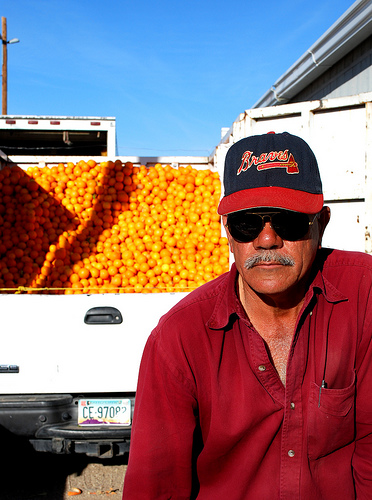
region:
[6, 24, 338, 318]
this man is selling fruit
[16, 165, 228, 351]
this is a lot of oranges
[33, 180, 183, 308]
these are all oranges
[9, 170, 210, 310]
these are citrusy fruits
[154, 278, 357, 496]
the man has a button up shirt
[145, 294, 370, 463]
the mans shirt is red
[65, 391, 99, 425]
the license plate starts with CE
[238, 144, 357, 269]
the man has a baseball hat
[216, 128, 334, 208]
the hat is for the "Braves"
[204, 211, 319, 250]
the man's nose is very red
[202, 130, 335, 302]
head of a person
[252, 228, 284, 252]
nose of a person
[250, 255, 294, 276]
mouth of a person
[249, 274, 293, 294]
jaw of a person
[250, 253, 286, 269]
lips of a person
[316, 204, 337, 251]
ear of a person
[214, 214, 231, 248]
ear of a person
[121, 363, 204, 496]
arm of a person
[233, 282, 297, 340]
neck of a person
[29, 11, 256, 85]
Sky is blue color.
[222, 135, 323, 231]
Man is wearing black and red cap.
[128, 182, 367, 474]
Man is wearing red shirt.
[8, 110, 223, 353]
truck is white color.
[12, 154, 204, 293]
Oranges are in truck.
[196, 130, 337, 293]
Man is wearing black glasses.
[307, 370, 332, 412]
Pen is in man shirt pocket.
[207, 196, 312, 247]
Eye glass are black color.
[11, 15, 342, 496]
Day time picture.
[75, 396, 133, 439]
Number plate is white and blue color.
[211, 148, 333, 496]
A man with black glasses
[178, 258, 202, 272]
A fresh orange in a truck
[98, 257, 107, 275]
A fresh orange in a truck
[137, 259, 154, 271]
A fresh orange in a truck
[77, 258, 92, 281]
A fresh orange in a truck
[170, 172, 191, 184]
A fresh orange in a truck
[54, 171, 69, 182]
A fresh orange in a truck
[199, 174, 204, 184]
A fresh orange in a truck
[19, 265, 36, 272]
A fresh orange in a truck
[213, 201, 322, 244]
A pair of black sunglasses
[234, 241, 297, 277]
Mustache on a man's face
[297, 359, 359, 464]
Red pocket of a shirt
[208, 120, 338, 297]
Hat on the man's head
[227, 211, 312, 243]
the sunglasses are the color black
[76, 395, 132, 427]
the pretty color license plate on the truck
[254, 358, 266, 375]
a button on a red shirt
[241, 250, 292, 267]
a grey mustache on a man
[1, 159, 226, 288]
a trunk full of oranges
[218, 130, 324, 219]
a red and black baseball cap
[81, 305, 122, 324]
a black handle with a key hole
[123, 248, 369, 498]
the man shirt is the color red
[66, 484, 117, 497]
an orange peel on the ground